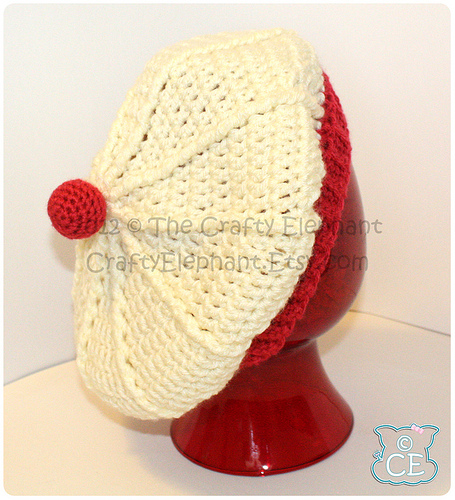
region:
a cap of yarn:
[38, 16, 361, 436]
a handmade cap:
[37, 17, 362, 428]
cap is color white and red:
[39, 16, 359, 436]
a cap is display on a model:
[41, 16, 387, 484]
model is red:
[163, 168, 378, 482]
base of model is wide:
[173, 356, 364, 477]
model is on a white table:
[11, 16, 451, 489]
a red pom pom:
[39, 173, 117, 247]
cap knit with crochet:
[38, 17, 359, 426]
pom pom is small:
[38, 169, 116, 243]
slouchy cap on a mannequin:
[31, 19, 371, 479]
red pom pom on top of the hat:
[40, 172, 113, 243]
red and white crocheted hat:
[35, 18, 348, 461]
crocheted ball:
[37, 175, 113, 241]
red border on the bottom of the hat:
[241, 86, 352, 388]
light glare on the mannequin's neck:
[263, 459, 271, 476]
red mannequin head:
[168, 143, 390, 482]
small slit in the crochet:
[278, 190, 296, 206]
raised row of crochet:
[102, 240, 163, 426]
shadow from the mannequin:
[319, 299, 367, 354]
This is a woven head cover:
[81, 316, 217, 425]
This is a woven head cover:
[85, 240, 264, 332]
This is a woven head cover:
[44, 195, 184, 300]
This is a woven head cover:
[194, 183, 320, 284]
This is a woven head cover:
[123, 115, 246, 212]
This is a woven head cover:
[252, 119, 346, 237]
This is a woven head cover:
[134, 87, 342, 139]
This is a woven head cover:
[208, 282, 299, 360]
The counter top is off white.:
[30, 402, 122, 484]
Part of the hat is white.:
[73, 245, 217, 375]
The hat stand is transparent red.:
[225, 376, 342, 454]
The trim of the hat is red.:
[314, 99, 345, 268]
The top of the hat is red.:
[41, 179, 112, 237]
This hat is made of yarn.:
[114, 112, 344, 240]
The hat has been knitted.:
[54, 9, 288, 362]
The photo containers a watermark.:
[363, 413, 443, 495]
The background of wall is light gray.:
[16, 22, 123, 129]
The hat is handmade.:
[47, 70, 359, 373]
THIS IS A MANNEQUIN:
[160, 134, 366, 483]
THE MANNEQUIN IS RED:
[161, 153, 378, 483]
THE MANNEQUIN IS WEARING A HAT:
[136, 145, 368, 479]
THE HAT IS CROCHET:
[32, 19, 370, 431]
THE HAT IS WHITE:
[43, 19, 359, 436]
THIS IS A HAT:
[32, 16, 376, 433]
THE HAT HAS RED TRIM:
[41, 21, 357, 438]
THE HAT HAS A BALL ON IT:
[43, 175, 109, 248]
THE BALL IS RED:
[46, 171, 118, 249]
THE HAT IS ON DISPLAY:
[30, 19, 360, 437]